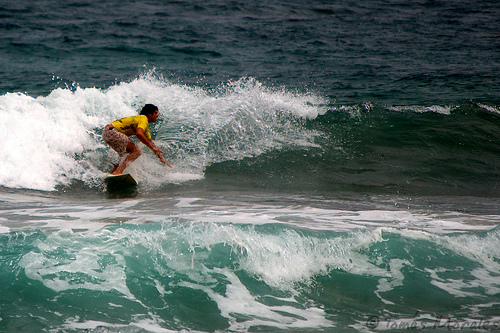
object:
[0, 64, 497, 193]
wave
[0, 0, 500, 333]
water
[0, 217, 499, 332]
wave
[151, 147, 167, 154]
hand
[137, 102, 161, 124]
head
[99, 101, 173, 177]
swimmer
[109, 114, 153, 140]
top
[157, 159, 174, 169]
hand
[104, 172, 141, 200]
surfboard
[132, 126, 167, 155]
arms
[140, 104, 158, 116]
hair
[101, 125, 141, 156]
shorts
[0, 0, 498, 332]
ocean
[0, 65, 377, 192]
foam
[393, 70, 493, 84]
wave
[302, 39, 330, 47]
wave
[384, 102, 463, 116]
foam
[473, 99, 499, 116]
foam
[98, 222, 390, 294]
foam